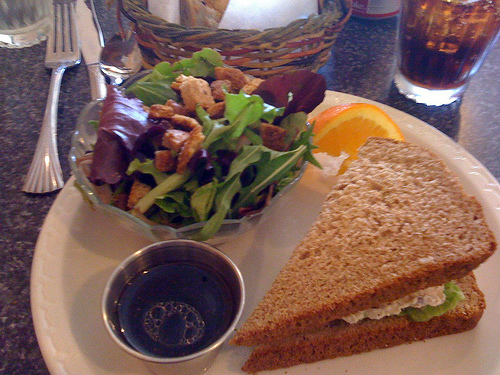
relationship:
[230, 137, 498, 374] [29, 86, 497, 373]
bread on plate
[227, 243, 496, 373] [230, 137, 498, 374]
crust of bread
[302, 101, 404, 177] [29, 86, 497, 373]
orange on plate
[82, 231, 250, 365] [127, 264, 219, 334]
cup has dressing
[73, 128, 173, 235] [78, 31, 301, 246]
bowl of salad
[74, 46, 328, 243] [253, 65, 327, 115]
salad has leaf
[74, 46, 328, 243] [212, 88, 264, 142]
salad has leaf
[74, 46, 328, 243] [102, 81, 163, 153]
salad has leaf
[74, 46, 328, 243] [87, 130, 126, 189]
salad has leaf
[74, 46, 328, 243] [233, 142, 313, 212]
salad has leaf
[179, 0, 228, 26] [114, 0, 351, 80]
bread in basket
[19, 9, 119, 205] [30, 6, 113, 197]
set of silverware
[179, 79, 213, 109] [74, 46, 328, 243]
crouton on salad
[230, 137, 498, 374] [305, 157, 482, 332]
bread use bread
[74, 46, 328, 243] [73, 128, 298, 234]
salad in bowl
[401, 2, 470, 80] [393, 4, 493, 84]
cola in beverage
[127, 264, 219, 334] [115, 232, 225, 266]
dressing in holder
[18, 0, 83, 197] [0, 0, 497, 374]
silverware on table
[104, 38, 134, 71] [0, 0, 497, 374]
silver on table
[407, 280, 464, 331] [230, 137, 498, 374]
lettuce in bread